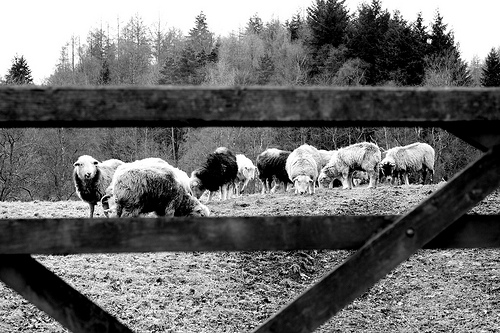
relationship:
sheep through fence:
[112, 158, 202, 219] [3, 71, 499, 331]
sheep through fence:
[67, 147, 119, 213] [3, 71, 499, 331]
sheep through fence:
[382, 142, 435, 182] [3, 71, 499, 331]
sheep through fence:
[317, 139, 380, 190] [3, 71, 499, 331]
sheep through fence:
[285, 143, 320, 193] [3, 71, 499, 331]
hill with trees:
[9, 19, 479, 202] [1, 0, 498, 201]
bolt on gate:
[402, 223, 418, 241] [319, 85, 489, 329]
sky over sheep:
[0, 2, 497, 86] [382, 142, 435, 182]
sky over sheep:
[0, 2, 497, 86] [317, 139, 380, 190]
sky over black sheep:
[0, 2, 497, 86] [254, 144, 293, 192]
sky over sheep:
[0, 2, 497, 86] [231, 152, 258, 193]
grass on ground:
[198, 273, 239, 324] [106, 261, 241, 309]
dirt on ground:
[120, 272, 153, 280] [106, 261, 241, 309]